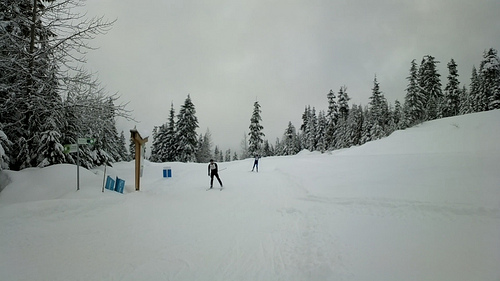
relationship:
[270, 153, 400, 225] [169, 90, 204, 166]
snow on tree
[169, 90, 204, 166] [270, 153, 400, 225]
tree in snow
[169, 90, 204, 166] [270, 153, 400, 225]
tree on snow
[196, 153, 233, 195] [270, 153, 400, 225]
person in snow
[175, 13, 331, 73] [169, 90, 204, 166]
sky above tree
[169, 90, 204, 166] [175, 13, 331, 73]
tree below sky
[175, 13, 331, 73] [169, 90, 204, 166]
sky near tree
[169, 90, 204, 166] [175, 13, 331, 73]
tree in sky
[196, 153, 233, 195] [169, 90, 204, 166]
person near tree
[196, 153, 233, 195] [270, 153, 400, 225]
person on snow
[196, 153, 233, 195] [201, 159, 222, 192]
person wearing clothing